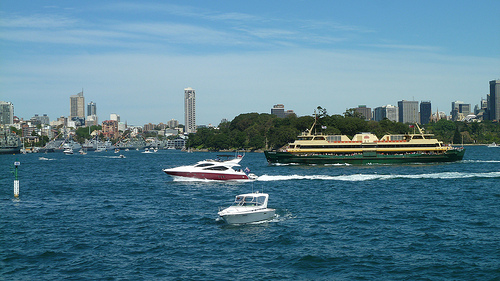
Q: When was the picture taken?
A: Daytime.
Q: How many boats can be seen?
A: Three.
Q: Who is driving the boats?
A: Captains.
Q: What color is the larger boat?
A: Green.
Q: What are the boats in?
A: Water.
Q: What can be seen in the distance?
A: Buildings.